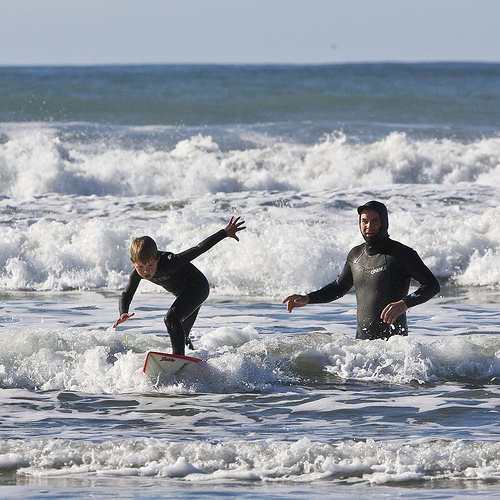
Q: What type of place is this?
A: It is an ocean.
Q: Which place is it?
A: It is an ocean.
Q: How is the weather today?
A: It is overcast.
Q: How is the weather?
A: It is overcast.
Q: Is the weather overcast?
A: Yes, it is overcast.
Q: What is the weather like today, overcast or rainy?
A: It is overcast.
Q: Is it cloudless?
A: No, it is overcast.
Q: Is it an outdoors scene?
A: Yes, it is outdoors.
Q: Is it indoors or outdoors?
A: It is outdoors.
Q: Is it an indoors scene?
A: No, it is outdoors.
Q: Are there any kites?
A: No, there are no kites.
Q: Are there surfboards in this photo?
A: Yes, there is a surfboard.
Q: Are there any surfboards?
A: Yes, there is a surfboard.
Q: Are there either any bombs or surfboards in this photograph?
A: Yes, there is a surfboard.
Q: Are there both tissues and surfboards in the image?
A: No, there is a surfboard but no tissues.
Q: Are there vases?
A: No, there are no vases.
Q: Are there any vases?
A: No, there are no vases.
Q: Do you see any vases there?
A: No, there are no vases.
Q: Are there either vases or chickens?
A: No, there are no vases or chickens.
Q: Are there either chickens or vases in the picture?
A: No, there are no vases or chickens.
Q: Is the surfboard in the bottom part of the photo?
A: Yes, the surfboard is in the bottom of the image.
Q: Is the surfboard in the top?
A: No, the surfboard is in the bottom of the image.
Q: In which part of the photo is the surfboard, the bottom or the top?
A: The surfboard is in the bottom of the image.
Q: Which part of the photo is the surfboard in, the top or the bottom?
A: The surfboard is in the bottom of the image.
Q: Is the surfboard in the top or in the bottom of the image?
A: The surfboard is in the bottom of the image.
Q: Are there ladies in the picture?
A: No, there are no ladies.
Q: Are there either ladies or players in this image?
A: No, there are no ladies or players.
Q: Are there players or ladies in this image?
A: No, there are no ladies or players.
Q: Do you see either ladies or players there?
A: No, there are no ladies or players.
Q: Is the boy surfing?
A: Yes, the boy is surfing.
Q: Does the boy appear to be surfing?
A: Yes, the boy is surfing.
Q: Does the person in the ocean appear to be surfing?
A: Yes, the boy is surfing.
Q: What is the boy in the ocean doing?
A: The boy is surfing.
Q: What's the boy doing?
A: The boy is surfing.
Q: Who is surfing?
A: The boy is surfing.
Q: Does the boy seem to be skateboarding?
A: No, the boy is surfing.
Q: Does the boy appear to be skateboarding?
A: No, the boy is surfing.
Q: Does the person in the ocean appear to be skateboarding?
A: No, the boy is surfing.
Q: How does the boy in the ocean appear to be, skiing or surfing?
A: The boy is surfing.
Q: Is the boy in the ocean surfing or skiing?
A: The boy is surfing.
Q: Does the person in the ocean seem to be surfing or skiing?
A: The boy is surfing.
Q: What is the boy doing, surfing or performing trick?
A: The boy is surfing.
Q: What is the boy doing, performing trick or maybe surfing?
A: The boy is surfing.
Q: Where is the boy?
A: The boy is in the ocean.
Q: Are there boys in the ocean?
A: Yes, there is a boy in the ocean.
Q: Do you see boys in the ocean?
A: Yes, there is a boy in the ocean.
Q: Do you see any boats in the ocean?
A: No, there is a boy in the ocean.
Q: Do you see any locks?
A: No, there are no locks.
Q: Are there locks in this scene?
A: No, there are no locks.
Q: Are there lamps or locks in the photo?
A: No, there are no locks or lamps.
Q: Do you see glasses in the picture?
A: No, there are no glasses.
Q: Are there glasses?
A: No, there are no glasses.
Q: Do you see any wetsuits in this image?
A: Yes, there is a wetsuit.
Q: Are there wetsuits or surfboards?
A: Yes, there is a wetsuit.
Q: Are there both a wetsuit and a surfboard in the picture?
A: Yes, there are both a wetsuit and a surfboard.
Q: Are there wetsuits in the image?
A: Yes, there is a wetsuit.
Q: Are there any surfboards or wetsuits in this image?
A: Yes, there is a wetsuit.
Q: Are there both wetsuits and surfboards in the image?
A: Yes, there are both a wetsuit and a surfboard.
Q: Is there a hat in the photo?
A: Yes, there is a hat.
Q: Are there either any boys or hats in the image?
A: Yes, there is a hat.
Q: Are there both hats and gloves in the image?
A: No, there is a hat but no gloves.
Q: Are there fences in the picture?
A: No, there are no fences.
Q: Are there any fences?
A: No, there are no fences.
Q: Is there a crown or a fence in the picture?
A: No, there are no fences or crowns.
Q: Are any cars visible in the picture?
A: No, there are no cars.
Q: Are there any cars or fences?
A: No, there are no cars or fences.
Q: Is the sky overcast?
A: Yes, the sky is overcast.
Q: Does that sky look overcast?
A: Yes, the sky is overcast.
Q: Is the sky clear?
A: No, the sky is overcast.